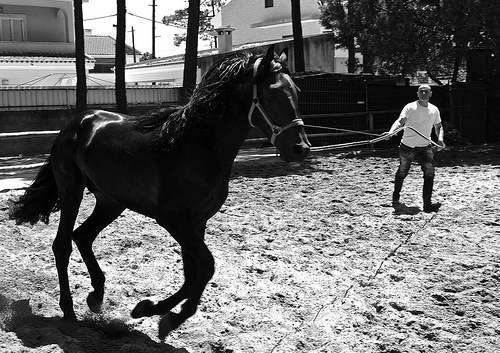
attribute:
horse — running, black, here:
[37, 39, 321, 330]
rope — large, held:
[300, 108, 415, 166]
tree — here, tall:
[364, 13, 476, 63]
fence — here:
[335, 76, 498, 133]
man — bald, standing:
[389, 70, 467, 207]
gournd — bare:
[258, 130, 362, 340]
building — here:
[17, 1, 259, 160]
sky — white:
[127, 2, 185, 64]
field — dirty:
[20, 88, 330, 323]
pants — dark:
[389, 132, 450, 243]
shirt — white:
[395, 95, 456, 154]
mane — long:
[164, 57, 233, 133]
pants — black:
[395, 153, 441, 221]